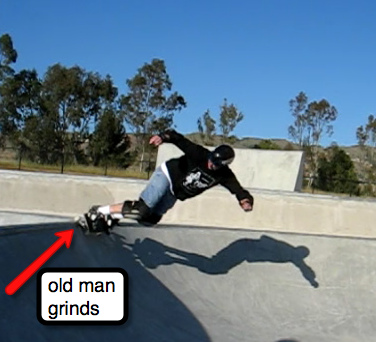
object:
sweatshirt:
[158, 130, 253, 206]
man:
[75, 129, 253, 237]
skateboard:
[75, 213, 111, 238]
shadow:
[111, 232, 319, 289]